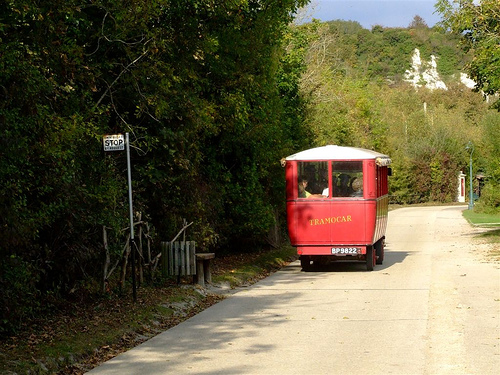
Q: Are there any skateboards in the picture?
A: No, there are no skateboards.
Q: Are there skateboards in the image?
A: No, there are no skateboards.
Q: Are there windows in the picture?
A: Yes, there is a window.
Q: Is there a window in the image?
A: Yes, there is a window.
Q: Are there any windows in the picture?
A: Yes, there is a window.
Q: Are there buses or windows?
A: Yes, there is a window.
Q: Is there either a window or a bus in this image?
A: Yes, there is a window.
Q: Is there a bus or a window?
A: Yes, there is a window.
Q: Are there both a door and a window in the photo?
A: No, there is a window but no doors.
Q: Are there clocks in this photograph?
A: No, there are no clocks.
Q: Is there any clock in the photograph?
A: No, there are no clocks.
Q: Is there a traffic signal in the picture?
A: No, there are no traffic lights.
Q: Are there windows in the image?
A: Yes, there is a window.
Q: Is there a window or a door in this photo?
A: Yes, there is a window.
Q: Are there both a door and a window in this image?
A: No, there is a window but no doors.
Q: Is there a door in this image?
A: No, there are no doors.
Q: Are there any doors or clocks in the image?
A: No, there are no doors or clocks.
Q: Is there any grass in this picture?
A: Yes, there is grass.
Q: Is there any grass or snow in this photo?
A: Yes, there is grass.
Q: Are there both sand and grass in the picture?
A: No, there is grass but no sand.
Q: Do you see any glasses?
A: No, there are no glasses.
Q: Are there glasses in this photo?
A: No, there are no glasses.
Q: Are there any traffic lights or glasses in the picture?
A: No, there are no glasses or traffic lights.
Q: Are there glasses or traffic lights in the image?
A: No, there are no glasses or traffic lights.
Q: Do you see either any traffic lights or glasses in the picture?
A: No, there are no glasses or traffic lights.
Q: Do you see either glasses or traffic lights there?
A: No, there are no glasses or traffic lights.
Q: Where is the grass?
A: The grass is on the ground.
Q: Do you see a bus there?
A: Yes, there is a bus.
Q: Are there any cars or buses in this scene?
A: Yes, there is a bus.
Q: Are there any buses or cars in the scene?
A: Yes, there is a bus.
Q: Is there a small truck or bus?
A: Yes, there is a small bus.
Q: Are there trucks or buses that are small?
A: Yes, the bus is small.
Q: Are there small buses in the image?
A: Yes, there is a small bus.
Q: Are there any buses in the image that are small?
A: Yes, there is a bus that is small.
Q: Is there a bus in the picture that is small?
A: Yes, there is a bus that is small.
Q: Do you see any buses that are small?
A: Yes, there is a bus that is small.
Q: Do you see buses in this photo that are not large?
A: Yes, there is a small bus.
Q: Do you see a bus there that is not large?
A: Yes, there is a small bus.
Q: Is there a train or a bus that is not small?
A: No, there is a bus but it is small.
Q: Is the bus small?
A: Yes, the bus is small.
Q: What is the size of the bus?
A: The bus is small.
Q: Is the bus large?
A: No, the bus is small.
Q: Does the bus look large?
A: No, the bus is small.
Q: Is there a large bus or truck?
A: No, there is a bus but it is small.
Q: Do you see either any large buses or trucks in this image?
A: No, there is a bus but it is small.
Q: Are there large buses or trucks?
A: No, there is a bus but it is small.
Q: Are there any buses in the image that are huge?
A: No, there is a bus but it is small.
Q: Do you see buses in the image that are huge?
A: No, there is a bus but it is small.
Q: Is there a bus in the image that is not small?
A: No, there is a bus but it is small.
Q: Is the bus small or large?
A: The bus is small.